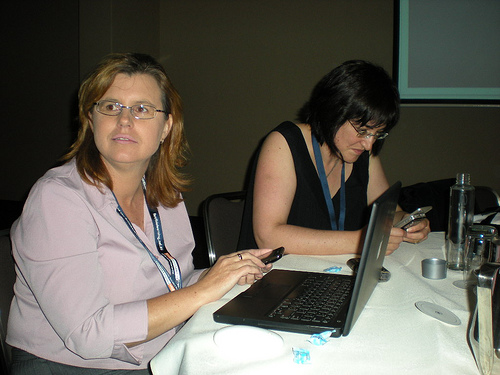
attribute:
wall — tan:
[2, 0, 82, 232]